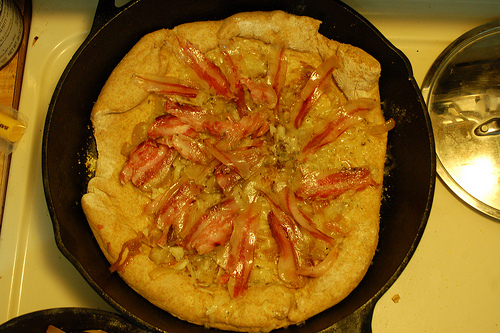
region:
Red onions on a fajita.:
[268, 189, 329, 244]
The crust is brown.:
[326, 267, 362, 290]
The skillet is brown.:
[408, 195, 458, 241]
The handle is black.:
[334, 310, 396, 329]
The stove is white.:
[36, 9, 86, 57]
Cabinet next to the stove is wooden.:
[0, 65, 39, 97]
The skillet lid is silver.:
[441, 78, 498, 185]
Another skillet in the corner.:
[26, 305, 179, 331]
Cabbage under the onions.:
[164, 247, 226, 277]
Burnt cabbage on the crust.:
[102, 233, 160, 278]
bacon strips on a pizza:
[203, 209, 281, 270]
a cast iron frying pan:
[406, 150, 431, 224]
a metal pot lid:
[438, 114, 485, 194]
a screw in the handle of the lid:
[471, 117, 487, 137]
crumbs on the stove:
[379, 289, 415, 305]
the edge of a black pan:
[31, 311, 76, 318]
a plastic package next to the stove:
[1, 102, 26, 146]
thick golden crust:
[327, 254, 371, 289]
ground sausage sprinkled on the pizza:
[271, 137, 288, 169]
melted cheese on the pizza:
[159, 255, 208, 285]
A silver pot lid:
[421, 11, 497, 223]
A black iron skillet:
[41, 4, 436, 331]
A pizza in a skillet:
[86, 11, 389, 330]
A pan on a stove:
[425, 11, 497, 222]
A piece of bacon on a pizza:
[122, 124, 182, 201]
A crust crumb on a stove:
[385, 290, 407, 307]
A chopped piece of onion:
[360, 116, 405, 141]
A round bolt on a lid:
[470, 122, 492, 137]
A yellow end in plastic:
[0, 107, 35, 152]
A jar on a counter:
[0, 0, 22, 70]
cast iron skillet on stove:
[43, 0, 465, 332]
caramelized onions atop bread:
[111, 38, 390, 265]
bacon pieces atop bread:
[121, 49, 380, 267]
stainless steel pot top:
[418, 15, 498, 223]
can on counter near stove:
[0, 1, 25, 68]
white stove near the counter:
[0, 0, 497, 326]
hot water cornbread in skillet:
[89, 13, 391, 331]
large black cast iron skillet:
[43, 0, 464, 332]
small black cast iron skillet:
[0, 308, 155, 331]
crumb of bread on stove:
[392, 294, 402, 306]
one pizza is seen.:
[30, 36, 386, 296]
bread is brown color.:
[100, 190, 125, 230]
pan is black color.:
[380, 195, 415, 235]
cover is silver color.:
[435, 115, 495, 180]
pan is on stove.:
[385, 225, 450, 300]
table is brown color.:
[0, 70, 25, 110]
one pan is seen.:
[45, 20, 425, 285]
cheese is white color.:
[321, 145, 361, 166]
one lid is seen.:
[437, 95, 490, 181]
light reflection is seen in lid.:
[433, 121, 498, 206]